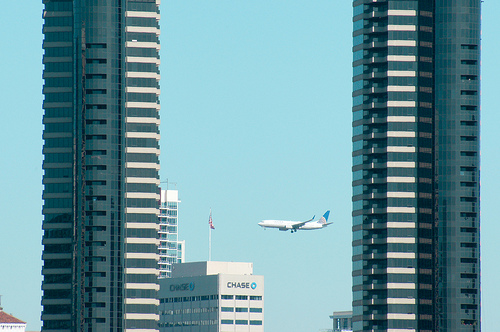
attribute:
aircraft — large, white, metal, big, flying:
[253, 209, 333, 234]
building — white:
[170, 263, 267, 328]